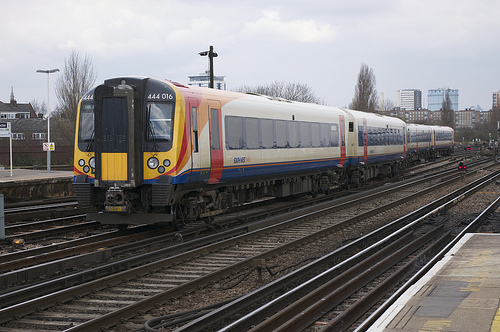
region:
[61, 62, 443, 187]
white train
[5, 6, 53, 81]
white clouds in blue sky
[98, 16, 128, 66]
white clouds in blue sky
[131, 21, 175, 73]
white clouds in blue sky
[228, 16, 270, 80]
white clouds in blue sky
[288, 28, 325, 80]
white clouds in blue sky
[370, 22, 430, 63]
white clouds in blue sky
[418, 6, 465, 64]
white clouds in blue sky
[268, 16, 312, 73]
white clouds in blue sky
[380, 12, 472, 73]
white clouds in blue sky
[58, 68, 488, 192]
white and yellow train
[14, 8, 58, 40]
white clouds in blue sky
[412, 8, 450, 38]
white clouds in blue sky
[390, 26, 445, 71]
white clouds in blue sky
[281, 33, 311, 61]
white clouds in blue sky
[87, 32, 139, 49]
white clouds in blue sky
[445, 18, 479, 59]
white clouds in blue sky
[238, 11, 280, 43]
white clouds in blue sky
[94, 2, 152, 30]
white clouds in blue sky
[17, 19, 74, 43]
white clouds in blue sky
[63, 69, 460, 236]
two trains at a railway station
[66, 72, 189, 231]
yellow and black front of a train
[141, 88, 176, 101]
number on the front of a train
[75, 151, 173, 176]
six lights on the front of a train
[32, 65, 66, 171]
street lamp on a railway platform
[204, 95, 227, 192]
red external door of a train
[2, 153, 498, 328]
metal railway tracks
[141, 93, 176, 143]
front windshield on a train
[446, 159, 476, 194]
small red lights between railway tracks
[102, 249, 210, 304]
wooden sleepers between railway tracks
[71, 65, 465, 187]
yellow and white train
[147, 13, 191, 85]
white clouds in blue sky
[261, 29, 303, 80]
white clouds in blue sky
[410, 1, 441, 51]
white clouds in blue sky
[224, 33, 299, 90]
white clouds in blue sky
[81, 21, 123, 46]
white clouds in blue sky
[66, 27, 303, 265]
this is a train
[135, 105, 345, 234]
the train is long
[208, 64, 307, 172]
these are some windows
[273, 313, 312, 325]
these are train tracks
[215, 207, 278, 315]
the tracks are metal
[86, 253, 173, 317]
the tracks are silver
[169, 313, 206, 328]
the tracks have rust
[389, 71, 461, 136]
these are some buildings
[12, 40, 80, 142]
this is a pole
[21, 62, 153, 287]
this is a white pole